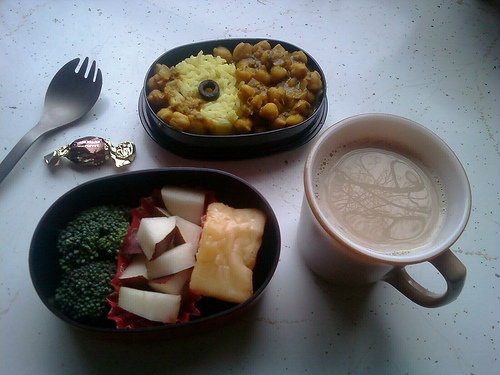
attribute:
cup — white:
[296, 111, 472, 309]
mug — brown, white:
[296, 125, 481, 320]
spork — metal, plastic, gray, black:
[8, 61, 97, 160]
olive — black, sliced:
[196, 79, 223, 105]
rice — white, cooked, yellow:
[171, 59, 230, 123]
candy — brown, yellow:
[38, 137, 139, 170]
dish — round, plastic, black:
[142, 108, 328, 158]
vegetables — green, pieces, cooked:
[64, 214, 117, 309]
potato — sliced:
[138, 202, 187, 313]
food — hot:
[74, 210, 267, 293]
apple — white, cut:
[150, 220, 188, 280]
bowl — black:
[26, 174, 299, 312]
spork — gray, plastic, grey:
[9, 58, 103, 123]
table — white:
[27, 17, 499, 286]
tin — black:
[26, 261, 281, 327]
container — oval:
[135, 39, 341, 161]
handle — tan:
[405, 258, 471, 308]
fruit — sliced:
[125, 188, 182, 318]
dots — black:
[345, 39, 484, 113]